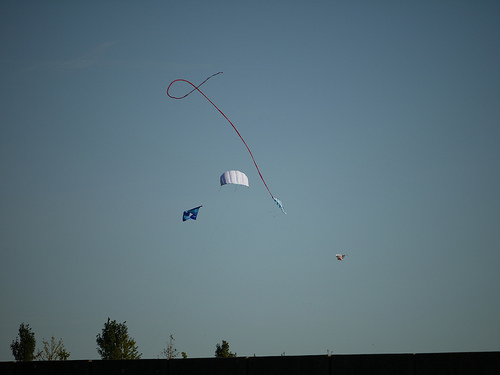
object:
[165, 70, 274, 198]
red tail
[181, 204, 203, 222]
kite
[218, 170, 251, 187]
kite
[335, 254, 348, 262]
colorful kite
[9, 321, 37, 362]
tree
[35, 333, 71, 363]
tree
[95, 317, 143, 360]
tree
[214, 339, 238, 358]
tree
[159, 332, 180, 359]
tree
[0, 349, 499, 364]
horizon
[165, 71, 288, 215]
kite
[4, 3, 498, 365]
clouds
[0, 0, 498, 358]
blue sky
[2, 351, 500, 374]
ground